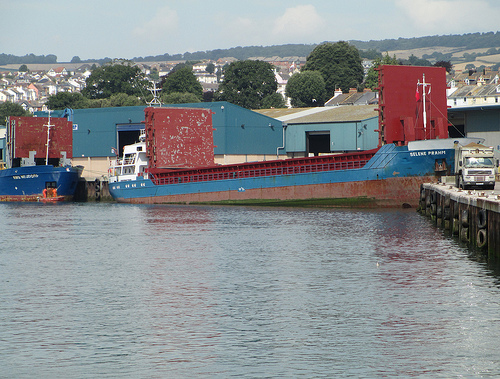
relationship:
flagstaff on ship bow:
[413, 73, 437, 140] [401, 136, 498, 218]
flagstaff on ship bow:
[41, 112, 56, 167] [21, 162, 85, 206]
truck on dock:
[454, 141, 500, 191] [409, 146, 499, 278]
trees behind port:
[290, 77, 327, 105] [1, 143, 498, 372]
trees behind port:
[305, 46, 362, 83] [1, 143, 498, 372]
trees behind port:
[225, 61, 287, 106] [1, 143, 498, 372]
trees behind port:
[157, 60, 192, 98] [1, 143, 498, 372]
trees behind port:
[86, 65, 143, 96] [1, 143, 498, 372]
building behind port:
[0, 99, 380, 181] [7, 109, 498, 379]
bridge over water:
[416, 180, 499, 271] [0, 193, 497, 369]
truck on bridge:
[450, 137, 497, 188] [418, 173, 498, 285]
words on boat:
[407, 148, 448, 157] [94, 135, 461, 207]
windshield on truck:
[464, 156, 494, 168] [452, 138, 496, 190]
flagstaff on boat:
[413, 73, 433, 140] [101, 60, 481, 211]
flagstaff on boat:
[41, 112, 56, 167] [1, 105, 83, 202]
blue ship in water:
[124, 140, 424, 215] [145, 307, 255, 372]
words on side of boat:
[410, 150, 446, 157] [105, 73, 482, 204]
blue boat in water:
[0, 163, 84, 202] [0, 193, 497, 369]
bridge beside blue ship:
[419, 185, 498, 272] [106, 137, 484, 210]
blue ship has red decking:
[106, 137, 484, 210] [152, 145, 404, 181]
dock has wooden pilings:
[421, 175, 484, 255] [422, 176, 499, 235]